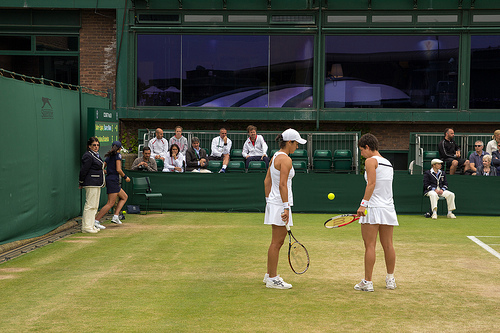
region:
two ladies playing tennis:
[249, 110, 415, 291]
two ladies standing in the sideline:
[72, 126, 146, 242]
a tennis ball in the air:
[299, 171, 344, 205]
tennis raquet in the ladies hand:
[286, 217, 314, 279]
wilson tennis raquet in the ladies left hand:
[319, 210, 374, 241]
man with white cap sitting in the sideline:
[414, 153, 489, 242]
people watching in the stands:
[129, 117, 261, 190]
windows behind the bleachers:
[136, 28, 495, 119]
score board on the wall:
[87, 106, 129, 145]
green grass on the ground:
[68, 256, 215, 324]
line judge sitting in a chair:
[419, 155, 459, 223]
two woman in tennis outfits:
[262, 117, 402, 305]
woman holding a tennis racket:
[263, 119, 315, 296]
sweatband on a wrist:
[353, 196, 370, 223]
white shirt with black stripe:
[358, 151, 403, 210]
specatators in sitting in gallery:
[125, 116, 272, 185]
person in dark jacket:
[75, 135, 113, 234]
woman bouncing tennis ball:
[320, 130, 405, 293]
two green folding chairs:
[310, 139, 358, 172]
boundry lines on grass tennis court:
[463, 221, 499, 264]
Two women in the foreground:
[226, 120, 416, 296]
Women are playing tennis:
[240, 118, 413, 298]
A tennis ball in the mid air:
[321, 185, 341, 204]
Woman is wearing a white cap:
[272, 124, 308, 151]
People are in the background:
[130, 123, 499, 184]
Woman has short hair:
[353, 131, 381, 161]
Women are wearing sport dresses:
[256, 150, 403, 230]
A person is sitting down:
[421, 154, 467, 217]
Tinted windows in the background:
[132, 33, 498, 112]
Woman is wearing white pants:
[77, 135, 109, 242]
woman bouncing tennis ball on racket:
[313, 116, 402, 298]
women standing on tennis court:
[258, 103, 418, 308]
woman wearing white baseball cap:
[261, 113, 319, 295]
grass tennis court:
[404, 207, 498, 332]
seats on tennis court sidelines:
[131, 116, 372, 293]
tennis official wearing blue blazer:
[413, 152, 468, 222]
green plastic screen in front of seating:
[119, 129, 492, 218]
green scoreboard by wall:
[87, 28, 129, 194]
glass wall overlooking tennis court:
[122, 25, 498, 250]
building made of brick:
[74, 13, 498, 174]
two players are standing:
[248, 98, 408, 310]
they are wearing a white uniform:
[233, 103, 428, 313]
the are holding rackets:
[243, 113, 448, 320]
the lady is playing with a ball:
[311, 124, 423, 309]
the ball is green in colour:
[318, 177, 350, 209]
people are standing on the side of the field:
[66, 125, 138, 235]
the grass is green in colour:
[135, 264, 247, 331]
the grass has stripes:
[438, 232, 492, 256]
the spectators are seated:
[130, 113, 272, 178]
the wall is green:
[13, 89, 65, 222]